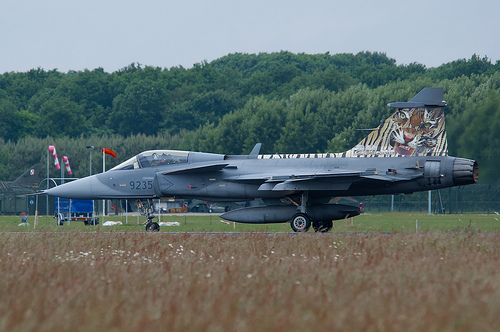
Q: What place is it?
A: It is a field.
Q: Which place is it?
A: It is a field.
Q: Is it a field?
A: Yes, it is a field.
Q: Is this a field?
A: Yes, it is a field.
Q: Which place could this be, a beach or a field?
A: It is a field.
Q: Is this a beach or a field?
A: It is a field.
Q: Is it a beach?
A: No, it is a field.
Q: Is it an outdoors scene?
A: Yes, it is outdoors.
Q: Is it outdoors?
A: Yes, it is outdoors.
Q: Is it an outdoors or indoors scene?
A: It is outdoors.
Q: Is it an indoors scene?
A: No, it is outdoors.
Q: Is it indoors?
A: No, it is outdoors.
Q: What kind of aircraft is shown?
A: The aircraft is a jet.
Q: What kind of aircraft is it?
A: The aircraft is a jet.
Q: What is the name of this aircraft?
A: This is a jet.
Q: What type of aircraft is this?
A: This is a jet.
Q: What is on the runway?
A: The jet is on the runway.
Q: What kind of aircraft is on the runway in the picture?
A: The aircraft is a jet.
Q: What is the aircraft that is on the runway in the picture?
A: The aircraft is a jet.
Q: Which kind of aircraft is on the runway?
A: The aircraft is a jet.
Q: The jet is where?
A: The jet is on the runway.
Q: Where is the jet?
A: The jet is on the runway.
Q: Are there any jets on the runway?
A: Yes, there is a jet on the runway.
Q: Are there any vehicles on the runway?
A: No, there is a jet on the runway.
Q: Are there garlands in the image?
A: No, there are no garlands.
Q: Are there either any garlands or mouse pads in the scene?
A: No, there are no garlands or mouse pads.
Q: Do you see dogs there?
A: No, there are no dogs.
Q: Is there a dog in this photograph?
A: No, there are no dogs.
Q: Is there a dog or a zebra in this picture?
A: No, there are no dogs or zebras.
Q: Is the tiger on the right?
A: Yes, the tiger is on the right of the image.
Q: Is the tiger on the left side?
A: No, the tiger is on the right of the image.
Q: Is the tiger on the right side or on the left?
A: The tiger is on the right of the image.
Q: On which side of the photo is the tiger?
A: The tiger is on the right of the image.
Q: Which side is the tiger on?
A: The tiger is on the right of the image.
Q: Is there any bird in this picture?
A: No, there are no birds.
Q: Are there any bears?
A: No, there are no bears.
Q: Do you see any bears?
A: No, there are no bears.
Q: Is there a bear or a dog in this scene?
A: No, there are no bears or dogs.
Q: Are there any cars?
A: No, there are no cars.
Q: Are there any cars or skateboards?
A: No, there are no cars or skateboards.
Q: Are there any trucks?
A: No, there are no trucks.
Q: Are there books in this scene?
A: No, there are no books.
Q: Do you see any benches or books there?
A: No, there are no books or benches.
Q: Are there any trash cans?
A: No, there are no trash cans.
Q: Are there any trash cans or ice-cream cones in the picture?
A: No, there are no trash cans or ice-cream cones.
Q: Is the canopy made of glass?
A: Yes, the canopy is made of glass.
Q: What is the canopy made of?
A: The canopy is made of glass.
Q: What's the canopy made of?
A: The canopy is made of glass.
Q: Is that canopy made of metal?
A: No, the canopy is made of glass.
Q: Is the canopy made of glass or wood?
A: The canopy is made of glass.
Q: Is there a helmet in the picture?
A: No, there are no helmets.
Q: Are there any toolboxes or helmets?
A: No, there are no helmets or toolboxes.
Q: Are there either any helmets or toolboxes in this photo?
A: No, there are no helmets or toolboxes.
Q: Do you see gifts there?
A: No, there are no gifts.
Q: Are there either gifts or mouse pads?
A: No, there are no gifts or mouse pads.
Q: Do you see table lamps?
A: No, there are no table lamps.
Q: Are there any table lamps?
A: No, there are no table lamps.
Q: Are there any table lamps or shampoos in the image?
A: No, there are no table lamps or shampoos.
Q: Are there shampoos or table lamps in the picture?
A: No, there are no table lamps or shampoos.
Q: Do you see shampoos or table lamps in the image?
A: No, there are no table lamps or shampoos.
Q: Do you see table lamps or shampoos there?
A: No, there are no table lamps or shampoos.